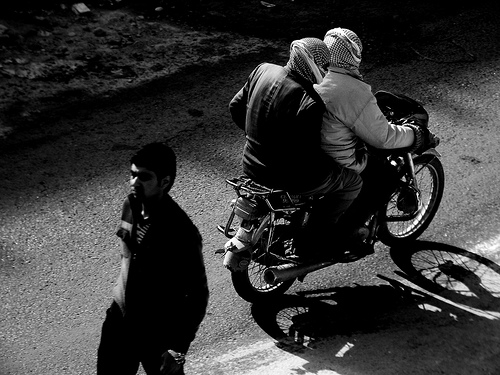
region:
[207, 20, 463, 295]
two people riding one motorcycle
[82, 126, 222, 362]
man walking along road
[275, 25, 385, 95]
people wearing checkered headcoverings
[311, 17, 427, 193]
driver wearing a light-colored jacket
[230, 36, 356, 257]
passenger wearing dark clothes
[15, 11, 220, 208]
shaded area to side of pedestrian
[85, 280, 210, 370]
hand in pant pocket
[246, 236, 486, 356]
motorcycle shadow on road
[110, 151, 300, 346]
exhaust pipe pointed at walker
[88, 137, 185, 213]
sun shining on half of a face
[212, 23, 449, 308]
two people on a motorcycle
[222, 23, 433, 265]
motorcyclists wearing headscarves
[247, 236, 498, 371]
shadow of a motorcycle on a road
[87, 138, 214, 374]
man is walking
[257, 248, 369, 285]
exhaust on a motorcycle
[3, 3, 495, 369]
image is black and white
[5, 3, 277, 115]
debris litters the side of the road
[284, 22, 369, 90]
headscarves wrapped around riders faces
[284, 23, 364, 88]
headscarves are checkered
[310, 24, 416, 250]
motorcyclist wears a pale colored jacket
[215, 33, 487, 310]
people on motorcycle.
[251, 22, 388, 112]
Hoods on the people.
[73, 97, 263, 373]
Man walking on the road.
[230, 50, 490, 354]
Bike on the road.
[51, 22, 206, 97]
Dirt by the side of the road.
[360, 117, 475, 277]
Wheels on the motorcycle.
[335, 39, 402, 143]
Person with white jacket.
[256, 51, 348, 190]
Person with black jacket.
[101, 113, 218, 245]
Man with black hair.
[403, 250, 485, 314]
Shadows on the road.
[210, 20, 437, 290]
these are two people on motorcycle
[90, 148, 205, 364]
this man is walking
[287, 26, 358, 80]
the two people are tying white clothes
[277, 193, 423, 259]
they are on a motorcycle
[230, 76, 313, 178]
the man is wearing a suit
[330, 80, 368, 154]
the motor cyclist has worn white jacket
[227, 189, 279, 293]
the motorist is metallic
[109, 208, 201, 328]
the man is wearing black jacket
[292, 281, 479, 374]
this is the motorcycles shadow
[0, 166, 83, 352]
the road is tarmacked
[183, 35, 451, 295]
2 people on a motorbike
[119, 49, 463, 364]
motorbike driving on road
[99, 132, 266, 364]
Man walking opposite way of motorbike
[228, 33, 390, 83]
2 people have on headwraps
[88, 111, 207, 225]
Man has dark hair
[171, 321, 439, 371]
Lines down the middle of the road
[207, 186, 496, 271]
2 wheels on bike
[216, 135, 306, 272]
Rack on the back of bike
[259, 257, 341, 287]
Metal exhaust on right side of bike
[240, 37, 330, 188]
person wearing dark jacket